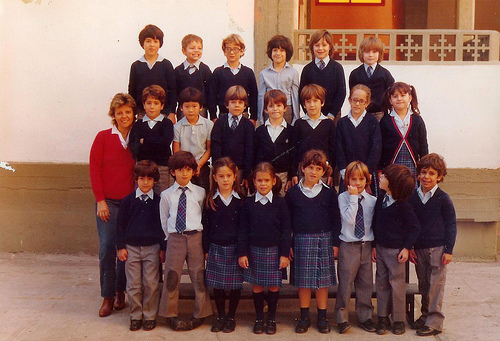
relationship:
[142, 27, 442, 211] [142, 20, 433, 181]
class of kids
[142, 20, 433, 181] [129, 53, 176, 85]
kids in uniform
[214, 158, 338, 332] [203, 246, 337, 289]
girls wearing skirts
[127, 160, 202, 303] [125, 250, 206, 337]
boys wearing khakis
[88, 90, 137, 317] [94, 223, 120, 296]
adult wearing jeans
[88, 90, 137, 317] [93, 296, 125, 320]
adult wearing boots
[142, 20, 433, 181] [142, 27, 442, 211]
kids in class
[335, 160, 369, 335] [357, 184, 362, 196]
boy has finger in mouth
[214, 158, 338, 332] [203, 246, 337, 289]
girls with skirts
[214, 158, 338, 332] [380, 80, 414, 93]
girls with pig tails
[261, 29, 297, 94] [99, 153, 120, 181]
kid without sweater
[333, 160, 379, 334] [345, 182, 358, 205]
boy holding uo fist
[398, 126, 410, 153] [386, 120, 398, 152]
red outline on sweater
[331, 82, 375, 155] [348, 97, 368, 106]
girl with glasses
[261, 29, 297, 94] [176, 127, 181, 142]
kid with short sleeves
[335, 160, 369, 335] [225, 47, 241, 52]
boy wearing eyeglasses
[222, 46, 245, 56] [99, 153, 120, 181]
girl has sweater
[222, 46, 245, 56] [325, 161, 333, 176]
girl wearing pony tail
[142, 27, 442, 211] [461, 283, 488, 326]
picture taken on pavement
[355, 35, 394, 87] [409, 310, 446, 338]
young boy standing on feet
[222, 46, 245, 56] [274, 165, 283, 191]
girl with pigtails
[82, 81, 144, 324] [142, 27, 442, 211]
adult next to group